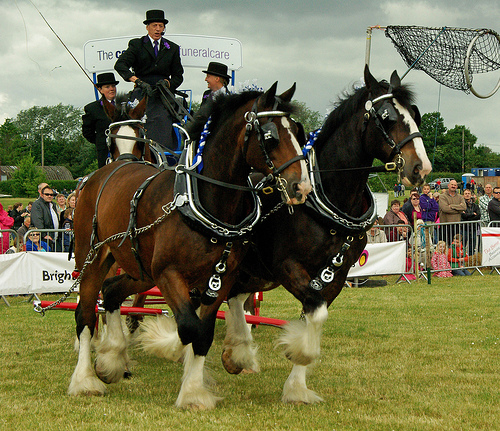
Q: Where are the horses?
A: On the grass.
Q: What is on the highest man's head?
A: A top hat.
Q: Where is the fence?
A: Behind the horses.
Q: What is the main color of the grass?
A: Green.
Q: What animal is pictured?
A: Horses.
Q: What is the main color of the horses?
A: Brown and white.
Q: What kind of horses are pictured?
A: Clydesdale.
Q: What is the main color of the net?
A: Black.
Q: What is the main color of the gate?
A: Silver.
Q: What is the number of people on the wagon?
A: 3.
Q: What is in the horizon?
A: Trees.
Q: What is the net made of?
A: Metal.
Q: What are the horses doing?
A: PErforming.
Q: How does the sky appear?
A: Cloudy.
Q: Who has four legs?
A: One horse.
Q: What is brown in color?
A: Horses.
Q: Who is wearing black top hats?
A: Three men.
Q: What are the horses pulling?
A: A carriage.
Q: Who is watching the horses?
A: Spectators.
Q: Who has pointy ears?
A: The horses.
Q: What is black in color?
A: Men's suits.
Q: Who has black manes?
A: Two horses.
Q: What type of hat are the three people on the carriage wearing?
A: Black top hot.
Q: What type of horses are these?
A: Clydesdale.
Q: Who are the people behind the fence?
A: Spectators.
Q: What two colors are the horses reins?
A: Silver and black.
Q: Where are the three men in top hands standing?
A: On carriage.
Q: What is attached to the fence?
A: White banners.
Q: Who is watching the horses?
A: People behind the fencing.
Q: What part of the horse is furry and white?
A: Hooves.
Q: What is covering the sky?
A: Thick grey and white clouds.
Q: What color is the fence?
A: Silver.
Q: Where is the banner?
A: On fence.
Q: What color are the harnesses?
A: Black.